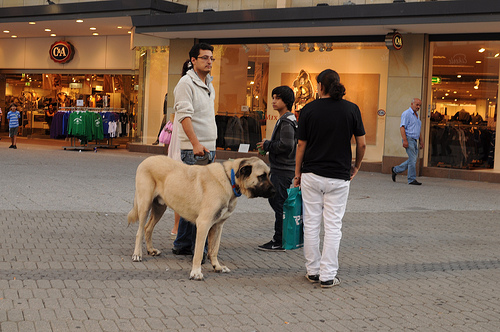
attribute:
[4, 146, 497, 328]
mall area — common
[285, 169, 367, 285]
pants — white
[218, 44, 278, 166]
window — shopping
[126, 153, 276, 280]
dog — large, breed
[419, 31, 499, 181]
window — large, store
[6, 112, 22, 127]
shirt — blue, white, striped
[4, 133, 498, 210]
concrete — grey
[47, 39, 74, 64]
sign — black, white, red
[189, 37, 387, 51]
lights — outdoor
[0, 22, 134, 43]
lights — outdoor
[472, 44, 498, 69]
lights — outdoor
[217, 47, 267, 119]
window — display, middle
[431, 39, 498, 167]
window — display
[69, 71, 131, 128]
window — display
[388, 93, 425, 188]
man — old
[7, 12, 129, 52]
fixtures — white, light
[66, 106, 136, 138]
shirts — colorful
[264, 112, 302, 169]
jacket — grey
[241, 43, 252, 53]
spotlight — overhead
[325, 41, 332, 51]
spotlight — overhead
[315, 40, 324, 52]
spotlight — overhead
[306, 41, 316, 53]
spotlight — overhead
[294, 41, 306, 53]
spotlight — overhead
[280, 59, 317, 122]
display — store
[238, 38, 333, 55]
spotlights — small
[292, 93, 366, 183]
shirt — black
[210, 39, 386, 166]
window — shopping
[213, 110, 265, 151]
rack — clothes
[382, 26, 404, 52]
sign — red, black, white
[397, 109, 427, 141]
shirt — blue